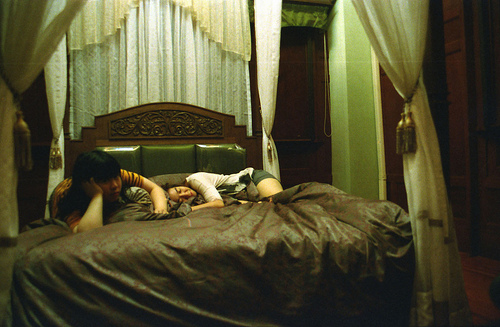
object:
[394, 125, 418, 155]
tassel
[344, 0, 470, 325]
curtain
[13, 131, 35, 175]
tassel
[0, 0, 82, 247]
curtain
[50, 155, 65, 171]
tassel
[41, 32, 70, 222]
curtain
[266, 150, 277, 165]
tassel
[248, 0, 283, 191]
curtain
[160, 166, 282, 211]
woman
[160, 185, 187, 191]
hair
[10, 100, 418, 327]
bed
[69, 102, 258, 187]
headboard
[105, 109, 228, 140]
design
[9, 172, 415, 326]
comforter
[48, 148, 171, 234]
guy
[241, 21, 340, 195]
door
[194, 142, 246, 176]
cushion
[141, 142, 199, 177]
cushion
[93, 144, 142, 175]
cushion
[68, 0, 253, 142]
curtain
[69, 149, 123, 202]
head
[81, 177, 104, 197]
hand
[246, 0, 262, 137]
post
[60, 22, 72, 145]
post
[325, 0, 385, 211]
wall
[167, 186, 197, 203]
face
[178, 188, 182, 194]
eye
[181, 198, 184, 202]
eye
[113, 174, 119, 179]
eye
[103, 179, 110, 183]
eye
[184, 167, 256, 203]
shirt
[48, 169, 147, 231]
shirt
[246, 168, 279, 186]
shorts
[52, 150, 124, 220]
hair